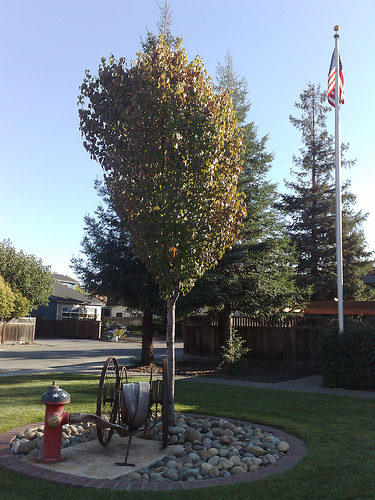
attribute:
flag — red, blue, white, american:
[326, 48, 347, 111]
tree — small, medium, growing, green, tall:
[76, 32, 251, 429]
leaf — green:
[100, 56, 108, 64]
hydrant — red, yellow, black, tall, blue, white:
[35, 379, 71, 467]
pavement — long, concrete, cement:
[2, 338, 375, 400]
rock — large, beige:
[278, 442, 290, 454]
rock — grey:
[16, 439, 39, 453]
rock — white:
[218, 447, 230, 457]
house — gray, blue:
[34, 271, 105, 320]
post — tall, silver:
[333, 24, 345, 334]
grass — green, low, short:
[0, 370, 375, 498]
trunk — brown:
[141, 309, 157, 366]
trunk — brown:
[217, 302, 235, 372]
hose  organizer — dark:
[94, 356, 170, 451]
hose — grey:
[71, 382, 152, 437]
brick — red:
[207, 476, 222, 489]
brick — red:
[156, 482, 172, 492]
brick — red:
[41, 468, 62, 480]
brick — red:
[128, 480, 146, 492]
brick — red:
[85, 475, 110, 490]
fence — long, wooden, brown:
[183, 314, 372, 372]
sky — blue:
[2, 2, 374, 286]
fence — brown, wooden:
[0, 314, 35, 346]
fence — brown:
[34, 318, 101, 341]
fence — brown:
[102, 315, 170, 334]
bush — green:
[320, 319, 373, 391]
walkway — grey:
[108, 363, 374, 403]